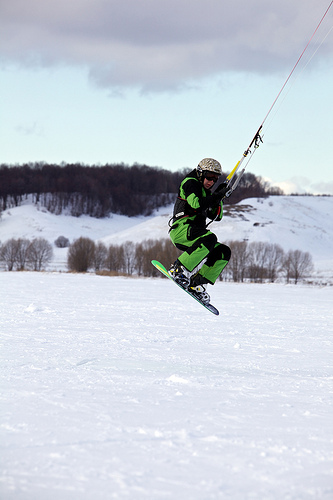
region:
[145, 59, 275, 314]
a person pulled into the air by cables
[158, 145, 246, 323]
a person with snowboard attached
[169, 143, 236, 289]
a person wearing green and black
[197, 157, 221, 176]
a person wearing a helmet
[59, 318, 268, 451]
an area of white snow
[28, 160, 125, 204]
trees without leaves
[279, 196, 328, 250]
snow on a hillside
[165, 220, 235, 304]
a person bending their knees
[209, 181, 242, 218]
a person holding a tether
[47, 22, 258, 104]
a cloud in the sky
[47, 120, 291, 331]
a snowboarder in the air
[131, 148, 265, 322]
this guy is flying in the air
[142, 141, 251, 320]
the snowboarder is wearing green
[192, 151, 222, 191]
this person is wearing a helmet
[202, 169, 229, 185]
this person is wearing black sunglasses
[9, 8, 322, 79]
storm clouds above the area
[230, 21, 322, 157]
a line that supports the snowboarder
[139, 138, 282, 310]
this snowboarder is being pulled by a plane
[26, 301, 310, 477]
this snow is rough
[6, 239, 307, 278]
trees in the environment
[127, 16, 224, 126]
this is the sky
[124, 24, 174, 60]
the sky has clouds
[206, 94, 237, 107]
the sky is blue in color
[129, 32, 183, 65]
the clouds are big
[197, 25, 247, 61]
the clouds are white in color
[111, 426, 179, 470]
this is the ground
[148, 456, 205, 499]
the ground has snow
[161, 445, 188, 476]
the snow is white in color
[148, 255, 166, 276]
this is a snowboard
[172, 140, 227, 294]
this is a person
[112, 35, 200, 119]
this is the sky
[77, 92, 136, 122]
the sky is blue in color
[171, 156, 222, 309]
this is lady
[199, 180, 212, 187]
the lady is light skinned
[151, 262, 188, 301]
this is a surfboard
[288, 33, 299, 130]
this is a string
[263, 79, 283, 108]
the string is red in color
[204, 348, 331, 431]
this is a snow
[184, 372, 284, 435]
the snow is white in color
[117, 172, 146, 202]
this is a forest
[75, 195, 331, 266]
mountain covered in snow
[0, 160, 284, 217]
lots of trees on a mountain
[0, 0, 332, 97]
clouds in the sky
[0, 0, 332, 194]
cloudy blue skies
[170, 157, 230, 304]
kid on a green suit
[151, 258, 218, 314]
green snowboard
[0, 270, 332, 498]
field covered in snow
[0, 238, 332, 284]
brown trees on the field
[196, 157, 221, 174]
multicolored helmet on a kid's head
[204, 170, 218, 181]
black sunglasses for snowboarding